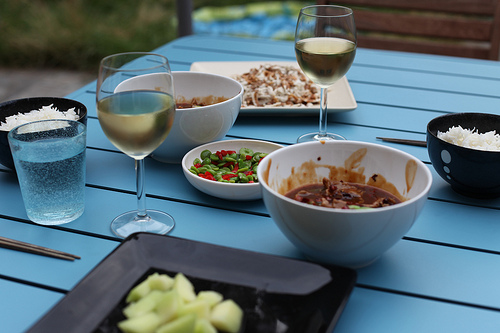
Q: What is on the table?
A: Dishes.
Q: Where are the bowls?
A: On the table.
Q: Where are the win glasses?
A: On the table.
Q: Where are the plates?
A: On the table.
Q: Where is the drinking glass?
A: On the table.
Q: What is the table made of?
A: Wood.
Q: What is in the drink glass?
A: Liquid.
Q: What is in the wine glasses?
A: Wine.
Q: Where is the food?
A: On the table.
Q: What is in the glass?
A: White wine.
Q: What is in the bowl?
A: Soup.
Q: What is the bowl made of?
A: Ceramic.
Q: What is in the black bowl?
A: Rice.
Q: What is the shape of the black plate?
A: Square.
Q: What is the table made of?
A: Wood.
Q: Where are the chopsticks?
A: On the table.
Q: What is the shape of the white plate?
A: Square.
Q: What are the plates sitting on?
A: A bright blue table.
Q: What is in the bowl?
A: Brown gravy and meat.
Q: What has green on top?
A: Black square bowl.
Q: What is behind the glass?
A: White round bowl with food.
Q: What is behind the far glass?
A: White square bowl with food.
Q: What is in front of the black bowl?
A: Clear glass with water.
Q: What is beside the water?
A: Tall clear half full glass.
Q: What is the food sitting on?
A: Large light blue table.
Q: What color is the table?
A: Blue.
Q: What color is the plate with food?
A: Black.